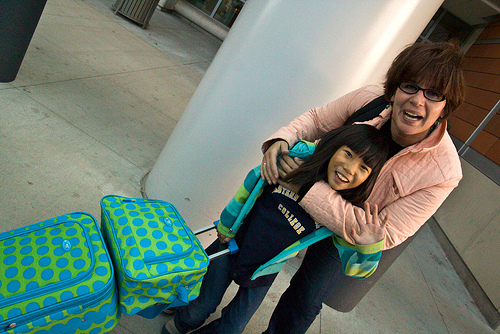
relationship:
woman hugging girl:
[349, 28, 453, 166] [264, 106, 378, 292]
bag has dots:
[107, 176, 218, 327] [139, 225, 165, 255]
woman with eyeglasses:
[349, 28, 453, 166] [389, 70, 450, 108]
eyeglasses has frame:
[389, 70, 450, 108] [410, 86, 444, 97]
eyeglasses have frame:
[389, 70, 450, 108] [410, 86, 444, 97]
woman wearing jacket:
[349, 28, 453, 166] [376, 127, 464, 272]